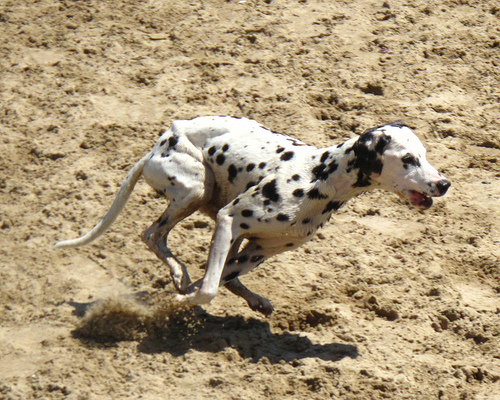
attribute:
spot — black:
[278, 150, 293, 160]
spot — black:
[207, 145, 215, 155]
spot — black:
[283, 240, 294, 247]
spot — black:
[158, 138, 169, 148]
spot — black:
[238, 222, 250, 229]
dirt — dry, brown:
[141, 24, 433, 91]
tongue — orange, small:
[405, 187, 424, 210]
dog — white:
[116, 73, 463, 335]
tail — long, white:
[53, 148, 153, 248]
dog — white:
[54, 108, 456, 319]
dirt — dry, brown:
[1, 3, 498, 395]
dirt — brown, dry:
[364, 294, 454, 344]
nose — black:
[433, 178, 451, 191]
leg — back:
[138, 154, 214, 298]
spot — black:
[393, 148, 418, 171]